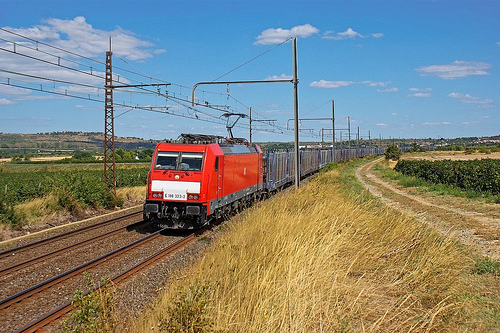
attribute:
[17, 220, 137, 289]
tracks — LONG, RAIL WAY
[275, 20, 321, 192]
poll — LONG, ELECTRIC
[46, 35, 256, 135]
wires — SMALL THING, ELECTRICAL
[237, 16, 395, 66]
clouds — small, white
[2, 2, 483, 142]
sky — clear, blue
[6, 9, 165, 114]
clouds — white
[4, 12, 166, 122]
clouds — white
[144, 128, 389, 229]
freight train — long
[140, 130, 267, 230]
engine — red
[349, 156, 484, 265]
road — dirt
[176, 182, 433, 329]
grass — tall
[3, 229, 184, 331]
tracks — rusted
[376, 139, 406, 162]
tree — small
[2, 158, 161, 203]
field — grassy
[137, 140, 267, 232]
car — red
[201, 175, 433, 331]
grass — high, brown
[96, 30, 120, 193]
power pole — old, rusted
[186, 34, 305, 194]
poles — curved, large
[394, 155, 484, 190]
growth — tall, green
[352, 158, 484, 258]
path — beaten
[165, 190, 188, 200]
numbers — black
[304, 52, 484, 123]
clouds — sparse, tiny, white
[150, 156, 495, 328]
grass — long, dry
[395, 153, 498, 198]
hedges — green